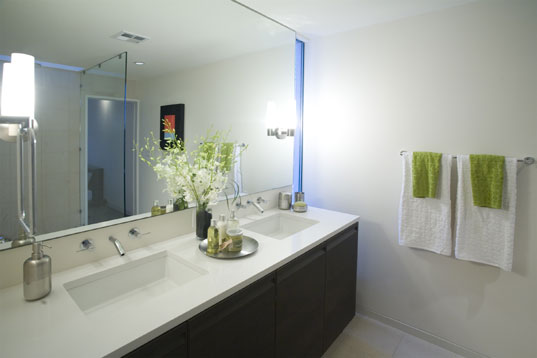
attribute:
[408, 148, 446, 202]
towel — hanging, green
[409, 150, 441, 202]
towel — small, green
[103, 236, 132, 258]
faucet — silver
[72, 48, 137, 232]
divider — glass